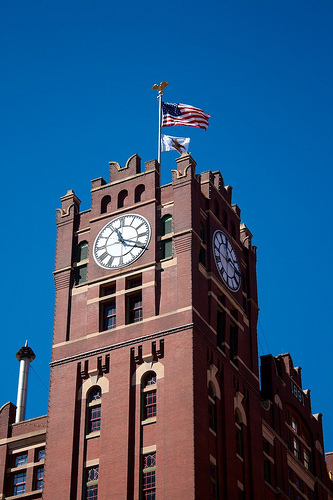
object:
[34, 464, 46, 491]
window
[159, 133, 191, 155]
flag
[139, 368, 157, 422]
window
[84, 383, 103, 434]
window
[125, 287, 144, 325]
window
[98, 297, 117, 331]
window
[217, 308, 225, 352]
window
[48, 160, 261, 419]
design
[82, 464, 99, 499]
window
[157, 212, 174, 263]
window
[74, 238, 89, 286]
window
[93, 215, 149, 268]
clock face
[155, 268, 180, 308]
brown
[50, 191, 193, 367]
frames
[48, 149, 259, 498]
tower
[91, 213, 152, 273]
clock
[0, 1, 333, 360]
sky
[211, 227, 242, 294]
clock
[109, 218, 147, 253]
time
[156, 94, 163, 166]
pole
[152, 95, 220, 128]
flag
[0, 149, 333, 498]
building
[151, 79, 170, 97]
eagle